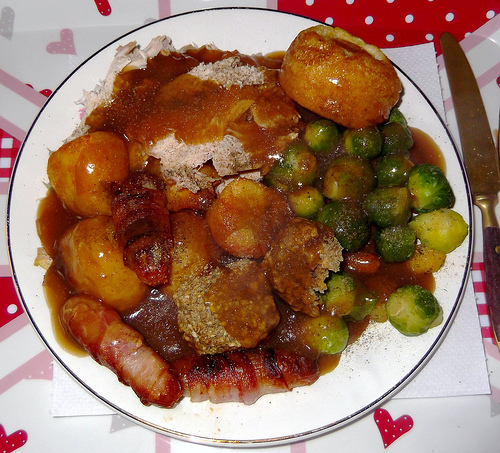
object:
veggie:
[302, 315, 349, 355]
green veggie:
[321, 271, 356, 318]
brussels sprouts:
[272, 126, 460, 233]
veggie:
[303, 130, 458, 262]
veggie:
[375, 227, 419, 263]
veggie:
[402, 165, 454, 210]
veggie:
[317, 201, 369, 252]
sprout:
[384, 285, 440, 335]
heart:
[368, 406, 414, 449]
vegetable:
[361, 186, 413, 227]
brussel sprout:
[407, 208, 468, 249]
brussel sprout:
[326, 162, 372, 197]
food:
[39, 23, 469, 408]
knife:
[439, 27, 499, 346]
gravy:
[37, 190, 84, 259]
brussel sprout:
[343, 127, 380, 156]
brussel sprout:
[379, 110, 414, 157]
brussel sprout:
[410, 208, 469, 254]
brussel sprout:
[360, 184, 415, 227]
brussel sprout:
[290, 185, 324, 215]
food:
[95, 179, 345, 339]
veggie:
[298, 115, 343, 154]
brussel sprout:
[386, 286, 443, 336]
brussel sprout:
[321, 268, 358, 319]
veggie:
[319, 154, 376, 203]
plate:
[6, 7, 473, 447]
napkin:
[387, 267, 493, 399]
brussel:
[377, 227, 416, 262]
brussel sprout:
[362, 186, 408, 225]